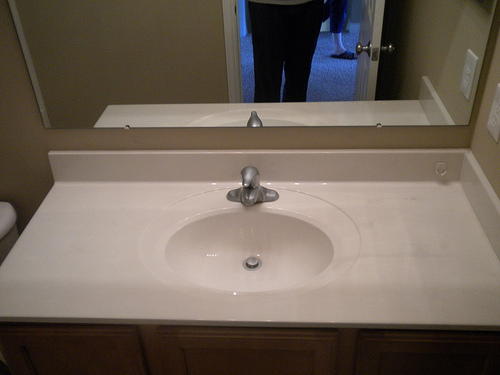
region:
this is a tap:
[228, 162, 293, 222]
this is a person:
[243, 5, 311, 100]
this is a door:
[354, 6, 401, 101]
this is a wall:
[29, 14, 218, 104]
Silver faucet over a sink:
[158, 158, 338, 298]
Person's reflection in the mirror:
[240, 0, 330, 105]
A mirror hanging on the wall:
[0, 0, 495, 130]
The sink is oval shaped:
[160, 200, 340, 297]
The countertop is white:
[0, 177, 495, 332]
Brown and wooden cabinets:
[1, 318, 499, 372]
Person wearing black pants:
[240, 0, 320, 105]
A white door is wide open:
[350, 0, 396, 105]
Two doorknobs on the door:
[348, 35, 398, 63]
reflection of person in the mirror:
[247, 0, 329, 102]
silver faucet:
[225, 169, 276, 207]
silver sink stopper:
[245, 257, 260, 269]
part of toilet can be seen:
[0, 201, 20, 260]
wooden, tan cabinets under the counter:
[0, 324, 498, 372]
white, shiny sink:
[142, 190, 357, 291]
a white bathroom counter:
[2, 151, 497, 328]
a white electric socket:
[485, 91, 497, 141]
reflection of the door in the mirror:
[352, 4, 396, 100]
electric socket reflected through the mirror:
[460, 50, 477, 97]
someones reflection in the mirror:
[222, 5, 352, 99]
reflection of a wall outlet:
[451, 39, 478, 114]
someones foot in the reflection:
[327, 25, 366, 71]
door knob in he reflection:
[349, 28, 398, 79]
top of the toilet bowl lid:
[5, 170, 28, 260]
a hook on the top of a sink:
[420, 150, 452, 179]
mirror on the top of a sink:
[6, 11, 489, 171]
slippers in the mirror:
[328, 48, 359, 68]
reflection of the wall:
[72, 19, 201, 103]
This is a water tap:
[216, 151, 288, 225]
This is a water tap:
[216, 127, 295, 263]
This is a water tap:
[216, 155, 301, 275]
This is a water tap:
[226, 72, 281, 158]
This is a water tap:
[221, 161, 281, 251]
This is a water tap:
[227, 167, 283, 218]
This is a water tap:
[231, 100, 266, 139]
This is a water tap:
[219, 152, 283, 224]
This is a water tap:
[214, 76, 306, 149]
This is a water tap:
[211, 155, 315, 256]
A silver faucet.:
[227, 164, 278, 206]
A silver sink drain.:
[244, 255, 261, 270]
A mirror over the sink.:
[7, 0, 497, 129]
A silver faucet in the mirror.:
[247, 110, 264, 127]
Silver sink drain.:
[244, 256, 260, 268]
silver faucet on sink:
[220, 160, 282, 215]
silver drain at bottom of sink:
[238, 252, 265, 273]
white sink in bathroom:
[141, 160, 365, 310]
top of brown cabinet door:
[151, 325, 344, 373]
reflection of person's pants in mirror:
[237, 0, 329, 104]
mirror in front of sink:
[3, 0, 498, 133]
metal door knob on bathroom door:
[350, 37, 375, 60]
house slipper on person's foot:
[323, 44, 359, 63]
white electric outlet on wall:
[453, 45, 482, 104]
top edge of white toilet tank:
[0, 197, 22, 262]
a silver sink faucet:
[226, 165, 280, 211]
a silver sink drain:
[244, 255, 259, 268]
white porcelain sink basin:
[161, 206, 337, 291]